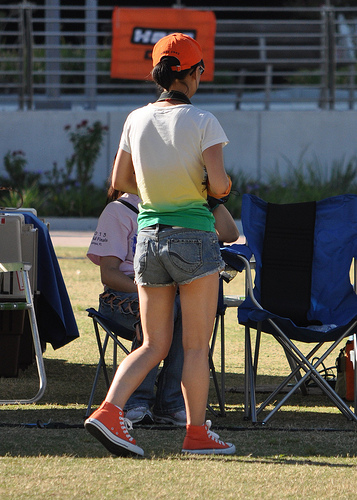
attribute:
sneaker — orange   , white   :
[85, 401, 240, 459]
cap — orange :
[147, 27, 202, 74]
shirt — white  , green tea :
[110, 93, 228, 230]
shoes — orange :
[86, 403, 236, 457]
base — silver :
[243, 330, 346, 416]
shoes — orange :
[81, 397, 236, 457]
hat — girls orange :
[148, 30, 207, 81]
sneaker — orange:
[180, 422, 237, 455]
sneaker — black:
[123, 406, 154, 428]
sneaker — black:
[154, 408, 187, 425]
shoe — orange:
[182, 421, 237, 455]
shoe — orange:
[82, 398, 144, 460]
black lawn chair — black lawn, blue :
[70, 252, 229, 397]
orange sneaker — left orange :
[75, 393, 246, 476]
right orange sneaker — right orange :
[178, 412, 238, 470]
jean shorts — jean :
[131, 217, 234, 293]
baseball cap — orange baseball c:
[143, 30, 213, 86]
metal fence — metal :
[3, 5, 355, 111]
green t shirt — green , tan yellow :
[104, 108, 256, 234]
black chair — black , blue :
[233, 205, 324, 341]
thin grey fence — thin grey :
[6, 1, 352, 109]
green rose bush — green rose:
[55, 111, 115, 191]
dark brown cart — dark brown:
[322, 331, 354, 407]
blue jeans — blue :
[126, 224, 231, 284]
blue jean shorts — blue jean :
[119, 219, 236, 286]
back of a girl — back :
[110, 108, 229, 290]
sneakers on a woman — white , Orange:
[82, 398, 270, 478]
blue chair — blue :
[219, 193, 353, 394]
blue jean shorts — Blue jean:
[129, 224, 230, 293]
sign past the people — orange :
[112, 9, 215, 85]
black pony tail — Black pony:
[149, 55, 178, 93]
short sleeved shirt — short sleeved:
[104, 97, 233, 231]